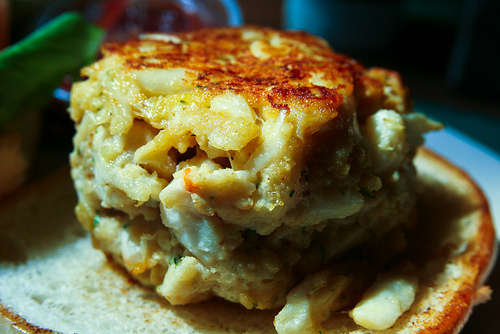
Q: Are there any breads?
A: Yes, there is a bread.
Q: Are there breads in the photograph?
A: Yes, there is a bread.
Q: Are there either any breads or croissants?
A: Yes, there is a bread.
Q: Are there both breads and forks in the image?
A: No, there is a bread but no forks.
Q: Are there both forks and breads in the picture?
A: No, there is a bread but no forks.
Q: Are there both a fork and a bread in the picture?
A: No, there is a bread but no forks.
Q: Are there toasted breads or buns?
A: Yes, there is a toasted bread.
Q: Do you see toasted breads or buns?
A: Yes, there is a toasted bread.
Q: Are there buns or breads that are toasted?
A: Yes, the bread is toasted.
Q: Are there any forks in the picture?
A: No, there are no forks.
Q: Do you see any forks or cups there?
A: No, there are no forks or cups.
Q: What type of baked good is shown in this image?
A: The baked good is a bread.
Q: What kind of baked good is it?
A: The food is a bread.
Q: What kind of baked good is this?
A: This is a bread.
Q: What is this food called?
A: This is a bread.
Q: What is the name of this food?
A: This is a bread.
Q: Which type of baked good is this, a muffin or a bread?
A: This is a bread.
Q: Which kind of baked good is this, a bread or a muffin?
A: This is a bread.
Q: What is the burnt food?
A: The food is a bread.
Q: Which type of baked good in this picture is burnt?
A: The baked good is a bread.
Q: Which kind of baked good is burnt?
A: The baked good is a bread.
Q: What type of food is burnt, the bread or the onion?
A: The bread is burnt.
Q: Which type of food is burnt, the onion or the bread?
A: The bread is burnt.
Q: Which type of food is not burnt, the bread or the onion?
A: The onion is not burnt.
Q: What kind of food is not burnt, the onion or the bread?
A: The onion is not burnt.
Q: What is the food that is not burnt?
A: The food is an onion.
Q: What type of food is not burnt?
A: The food is an onion.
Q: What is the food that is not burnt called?
A: The food is an onion.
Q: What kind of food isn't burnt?
A: The food is an onion.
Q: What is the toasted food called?
A: The food is a bread.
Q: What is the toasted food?
A: The food is a bread.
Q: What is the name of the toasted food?
A: The food is a bread.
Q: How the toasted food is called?
A: The food is a bread.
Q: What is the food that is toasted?
A: The food is a bread.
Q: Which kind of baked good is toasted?
A: The baked good is a bread.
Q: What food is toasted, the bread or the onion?
A: The bread is toasted.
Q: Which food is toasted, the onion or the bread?
A: The bread is toasted.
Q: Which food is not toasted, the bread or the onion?
A: The onion is not toasted.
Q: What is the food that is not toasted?
A: The food is an onion.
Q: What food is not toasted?
A: The food is an onion.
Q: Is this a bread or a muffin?
A: This is a bread.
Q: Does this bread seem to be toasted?
A: Yes, the bread is toasted.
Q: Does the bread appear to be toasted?
A: Yes, the bread is toasted.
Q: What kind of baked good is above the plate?
A: The food is a bread.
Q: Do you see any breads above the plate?
A: Yes, there is a bread above the plate.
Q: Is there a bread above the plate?
A: Yes, there is a bread above the plate.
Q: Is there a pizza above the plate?
A: No, there is a bread above the plate.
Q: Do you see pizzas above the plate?
A: No, there is a bread above the plate.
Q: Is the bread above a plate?
A: Yes, the bread is above a plate.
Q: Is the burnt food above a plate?
A: Yes, the bread is above a plate.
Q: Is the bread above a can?
A: No, the bread is above a plate.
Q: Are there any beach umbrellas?
A: No, there are no beach umbrellas.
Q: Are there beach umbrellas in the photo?
A: No, there are no beach umbrellas.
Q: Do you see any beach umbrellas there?
A: No, there are no beach umbrellas.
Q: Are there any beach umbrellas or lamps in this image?
A: No, there are no beach umbrellas or lamps.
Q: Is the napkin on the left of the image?
A: Yes, the napkin is on the left of the image.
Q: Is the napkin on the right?
A: No, the napkin is on the left of the image.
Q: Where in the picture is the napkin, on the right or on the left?
A: The napkin is on the left of the image.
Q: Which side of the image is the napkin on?
A: The napkin is on the left of the image.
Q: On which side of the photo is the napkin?
A: The napkin is on the left of the image.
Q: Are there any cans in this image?
A: No, there are no cans.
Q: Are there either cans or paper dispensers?
A: No, there are no cans or paper dispensers.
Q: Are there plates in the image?
A: Yes, there is a plate.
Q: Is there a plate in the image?
A: Yes, there is a plate.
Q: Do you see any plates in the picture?
A: Yes, there is a plate.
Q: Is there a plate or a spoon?
A: Yes, there is a plate.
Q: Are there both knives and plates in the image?
A: No, there is a plate but no knives.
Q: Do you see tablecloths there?
A: No, there are no tablecloths.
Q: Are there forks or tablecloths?
A: No, there are no tablecloths or forks.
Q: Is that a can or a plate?
A: That is a plate.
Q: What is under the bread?
A: The plate is under the bread.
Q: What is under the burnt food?
A: The plate is under the bread.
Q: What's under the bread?
A: The plate is under the bread.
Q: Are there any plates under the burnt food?
A: Yes, there is a plate under the bread.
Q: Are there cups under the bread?
A: No, there is a plate under the bread.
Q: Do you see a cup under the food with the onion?
A: No, there is a plate under the bread.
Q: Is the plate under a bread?
A: Yes, the plate is under a bread.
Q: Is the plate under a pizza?
A: No, the plate is under a bread.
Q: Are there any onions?
A: Yes, there is an onion.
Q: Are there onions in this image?
A: Yes, there is an onion.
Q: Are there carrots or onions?
A: Yes, there is an onion.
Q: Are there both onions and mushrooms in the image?
A: No, there is an onion but no mushrooms.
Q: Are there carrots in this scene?
A: No, there are no carrots.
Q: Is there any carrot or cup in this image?
A: No, there are no carrots or cups.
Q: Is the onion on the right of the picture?
A: Yes, the onion is on the right of the image.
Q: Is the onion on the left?
A: No, the onion is on the right of the image.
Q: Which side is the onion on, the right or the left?
A: The onion is on the right of the image.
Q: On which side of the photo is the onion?
A: The onion is on the right of the image.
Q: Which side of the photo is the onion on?
A: The onion is on the right of the image.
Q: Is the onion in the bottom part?
A: Yes, the onion is in the bottom of the image.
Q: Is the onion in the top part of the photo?
A: No, the onion is in the bottom of the image.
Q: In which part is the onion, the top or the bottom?
A: The onion is in the bottom of the image.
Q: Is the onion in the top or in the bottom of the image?
A: The onion is in the bottom of the image.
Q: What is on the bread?
A: The onion is on the bread.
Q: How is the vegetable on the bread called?
A: The vegetable is an onion.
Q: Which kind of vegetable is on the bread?
A: The vegetable is an onion.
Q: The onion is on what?
A: The onion is on the bread.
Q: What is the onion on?
A: The onion is on the bread.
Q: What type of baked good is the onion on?
A: The onion is on the bread.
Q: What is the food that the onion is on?
A: The food is a bread.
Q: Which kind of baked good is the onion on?
A: The onion is on the bread.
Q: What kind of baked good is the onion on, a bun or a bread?
A: The onion is on a bread.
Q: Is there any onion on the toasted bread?
A: Yes, there is an onion on the bread.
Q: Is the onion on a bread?
A: Yes, the onion is on a bread.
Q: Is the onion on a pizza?
A: No, the onion is on a bread.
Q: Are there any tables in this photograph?
A: Yes, there is a table.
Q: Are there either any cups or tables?
A: Yes, there is a table.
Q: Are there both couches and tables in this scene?
A: No, there is a table but no couches.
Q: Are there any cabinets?
A: No, there are no cabinets.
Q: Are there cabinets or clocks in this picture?
A: No, there are no cabinets or clocks.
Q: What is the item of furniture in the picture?
A: The piece of furniture is a table.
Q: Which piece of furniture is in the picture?
A: The piece of furniture is a table.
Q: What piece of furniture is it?
A: The piece of furniture is a table.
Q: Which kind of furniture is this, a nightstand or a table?
A: That is a table.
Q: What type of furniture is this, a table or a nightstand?
A: That is a table.